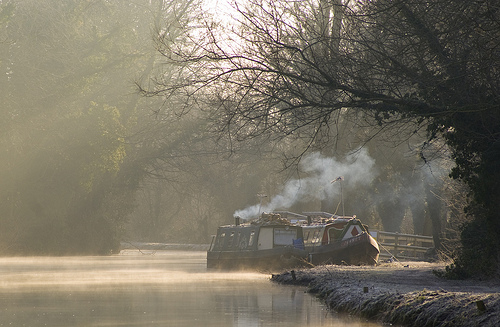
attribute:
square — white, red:
[338, 218, 360, 249]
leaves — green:
[2, 2, 199, 242]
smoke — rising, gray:
[231, 150, 386, 221]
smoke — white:
[233, 145, 458, 232]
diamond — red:
[348, 225, 360, 237]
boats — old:
[199, 205, 384, 279]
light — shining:
[328, 258, 440, 271]